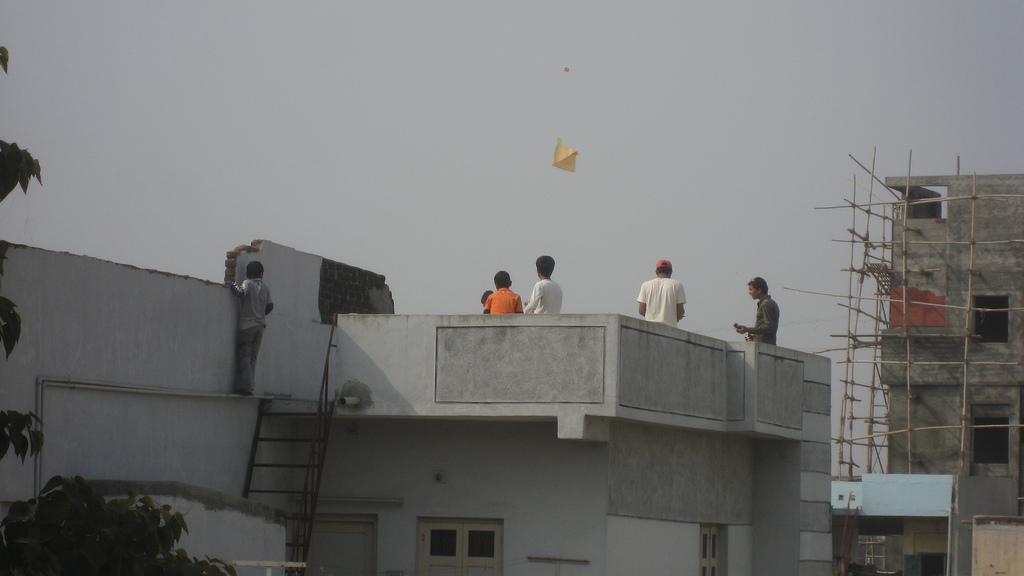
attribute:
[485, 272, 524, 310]
shirt — orange